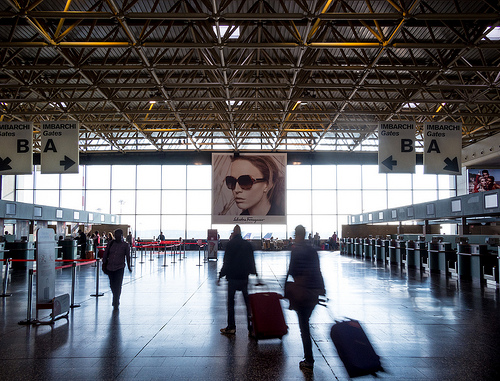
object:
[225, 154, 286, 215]
woman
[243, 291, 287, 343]
suitcase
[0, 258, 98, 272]
rope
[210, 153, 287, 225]
billboard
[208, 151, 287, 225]
picture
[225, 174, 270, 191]
sunglasses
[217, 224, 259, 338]
man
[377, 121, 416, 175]
sign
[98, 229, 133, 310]
people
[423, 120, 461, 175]
sign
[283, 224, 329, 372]
person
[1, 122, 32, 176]
sign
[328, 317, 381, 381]
bag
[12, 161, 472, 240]
windows